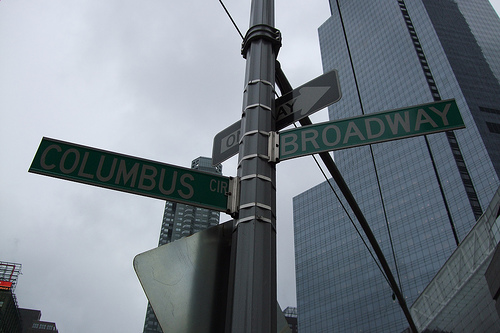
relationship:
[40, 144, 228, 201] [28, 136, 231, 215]
writing on street sign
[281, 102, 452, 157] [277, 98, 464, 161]
writing on street sign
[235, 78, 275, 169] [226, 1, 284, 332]
sign on pole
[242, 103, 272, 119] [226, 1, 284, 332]
ring on pole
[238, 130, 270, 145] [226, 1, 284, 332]
ring on pole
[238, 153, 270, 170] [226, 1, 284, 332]
ring on pole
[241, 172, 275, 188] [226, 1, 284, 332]
ring on pole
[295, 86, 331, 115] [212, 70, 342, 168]
arrow on sign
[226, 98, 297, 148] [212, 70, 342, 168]
writing on sign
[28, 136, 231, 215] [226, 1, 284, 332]
street sign on pole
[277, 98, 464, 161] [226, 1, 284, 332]
street sign on pole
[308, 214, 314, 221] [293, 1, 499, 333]
window on building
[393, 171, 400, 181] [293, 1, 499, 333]
window on building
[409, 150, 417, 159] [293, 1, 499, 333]
window on building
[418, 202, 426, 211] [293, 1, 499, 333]
window on building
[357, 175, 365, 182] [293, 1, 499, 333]
window on building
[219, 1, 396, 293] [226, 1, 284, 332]
wire attached to pole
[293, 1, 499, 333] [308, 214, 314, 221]
building has window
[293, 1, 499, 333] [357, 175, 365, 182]
building has window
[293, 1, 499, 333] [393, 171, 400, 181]
building has window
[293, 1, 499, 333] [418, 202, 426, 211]
building has window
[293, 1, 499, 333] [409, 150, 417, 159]
building has window